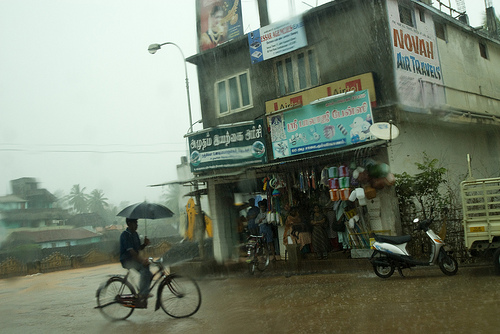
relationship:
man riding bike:
[116, 214, 156, 309] [89, 251, 206, 326]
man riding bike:
[117, 217, 150, 307] [89, 251, 206, 326]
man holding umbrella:
[117, 217, 150, 307] [114, 196, 179, 224]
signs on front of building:
[181, 120, 271, 171] [186, 4, 498, 264]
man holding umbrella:
[117, 217, 150, 307] [117, 199, 174, 243]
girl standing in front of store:
[307, 201, 335, 268] [174, 2, 449, 286]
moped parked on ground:
[365, 219, 455, 281] [0, 268, 500, 333]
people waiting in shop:
[238, 195, 332, 271] [192, 137, 399, 270]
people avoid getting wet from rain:
[238, 195, 332, 271] [1, 3, 499, 332]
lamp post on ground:
[154, 34, 223, 246] [0, 268, 500, 333]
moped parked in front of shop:
[368, 217, 458, 279] [178, 144, 399, 273]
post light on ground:
[148, 41, 199, 199] [0, 268, 500, 333]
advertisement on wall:
[376, 27, 442, 92] [384, 1, 498, 123]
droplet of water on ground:
[373, 295, 378, 300] [0, 268, 500, 333]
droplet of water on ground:
[419, 285, 422, 287] [0, 268, 500, 333]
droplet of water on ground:
[319, 290, 322, 292] [0, 268, 500, 333]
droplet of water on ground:
[476, 304, 480, 306] [0, 268, 500, 333]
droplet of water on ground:
[325, 307, 327, 310] [0, 268, 500, 333]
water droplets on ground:
[220, 272, 498, 332] [0, 268, 500, 333]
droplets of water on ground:
[248, 297, 265, 314] [0, 268, 500, 333]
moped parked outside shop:
[368, 217, 458, 279] [178, 144, 399, 273]